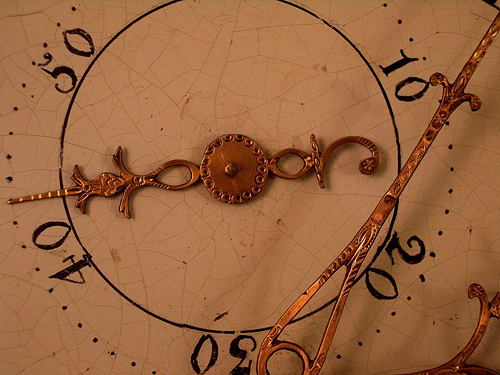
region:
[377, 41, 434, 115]
number 10 printed out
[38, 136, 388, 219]
The dial is golf.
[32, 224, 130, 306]
The numbers are black.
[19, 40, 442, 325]
The circle is black.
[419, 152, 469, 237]
The dots are black.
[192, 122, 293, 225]
The circle is gold.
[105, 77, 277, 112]
The background is tan.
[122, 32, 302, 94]
The background is cracked.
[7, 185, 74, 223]
The dial is pointy.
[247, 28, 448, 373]
The decoration is gold.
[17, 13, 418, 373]
The numbers are counting by 10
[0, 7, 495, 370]
the face of an old clock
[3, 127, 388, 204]
the pointer is brass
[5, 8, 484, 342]
the background is marble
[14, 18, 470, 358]
the background is cracked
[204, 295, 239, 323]
a mark on the marble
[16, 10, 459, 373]
the numbers are black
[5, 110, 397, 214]
pointer just past 40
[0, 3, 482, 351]
dots show minutes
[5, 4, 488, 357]
dots behind the numbers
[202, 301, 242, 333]
speck on the marble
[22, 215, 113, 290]
the number forty in black paint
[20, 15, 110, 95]
the number fifty in black paint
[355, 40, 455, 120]
the number ten in black paint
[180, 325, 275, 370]
the number thirty in black paint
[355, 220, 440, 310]
the number twenty in black paint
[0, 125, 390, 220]
a clock hand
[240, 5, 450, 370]
part of a clock hand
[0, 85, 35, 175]
a gradient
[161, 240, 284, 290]
antique paint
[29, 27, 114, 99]
Number 50 on clock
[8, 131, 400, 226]
Golden dial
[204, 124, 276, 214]
Golden circle in middle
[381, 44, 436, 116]
Number 10 on clock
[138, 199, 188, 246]
Small cracks in the face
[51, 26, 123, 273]
Part of circle's edge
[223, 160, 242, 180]
Little protuberance in center of circle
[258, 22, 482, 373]
Another golden dial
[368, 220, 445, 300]
Number 20 on the clock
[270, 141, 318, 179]
Reflective hoop in the dial